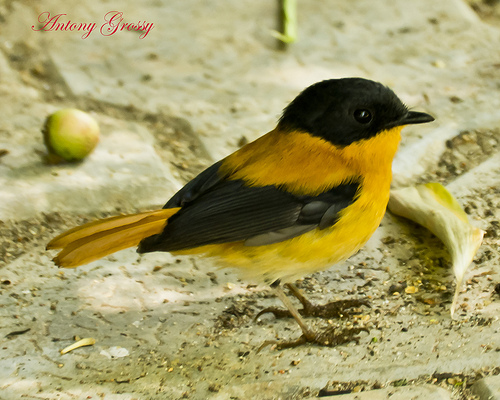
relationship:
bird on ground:
[44, 78, 435, 351] [1, 2, 500, 400]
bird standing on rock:
[44, 78, 435, 351] [166, 271, 445, 398]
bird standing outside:
[44, 78, 435, 351] [1, 2, 500, 399]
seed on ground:
[158, 350, 232, 383] [1, 2, 500, 400]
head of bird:
[269, 78, 407, 161] [44, 78, 435, 351]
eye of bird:
[355, 107, 372, 125] [44, 78, 435, 351]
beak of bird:
[401, 111, 434, 126] [44, 78, 435, 351]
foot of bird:
[256, 327, 370, 356] [44, 78, 435, 351]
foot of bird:
[254, 297, 370, 324] [44, 78, 435, 351]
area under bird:
[51, 280, 491, 400] [44, 78, 435, 351]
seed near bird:
[158, 350, 232, 383] [44, 78, 435, 351]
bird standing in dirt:
[44, 78, 435, 351] [192, 278, 422, 388]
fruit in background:
[42, 108, 100, 161] [1, 1, 499, 175]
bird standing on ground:
[44, 78, 435, 351] [1, 2, 500, 400]